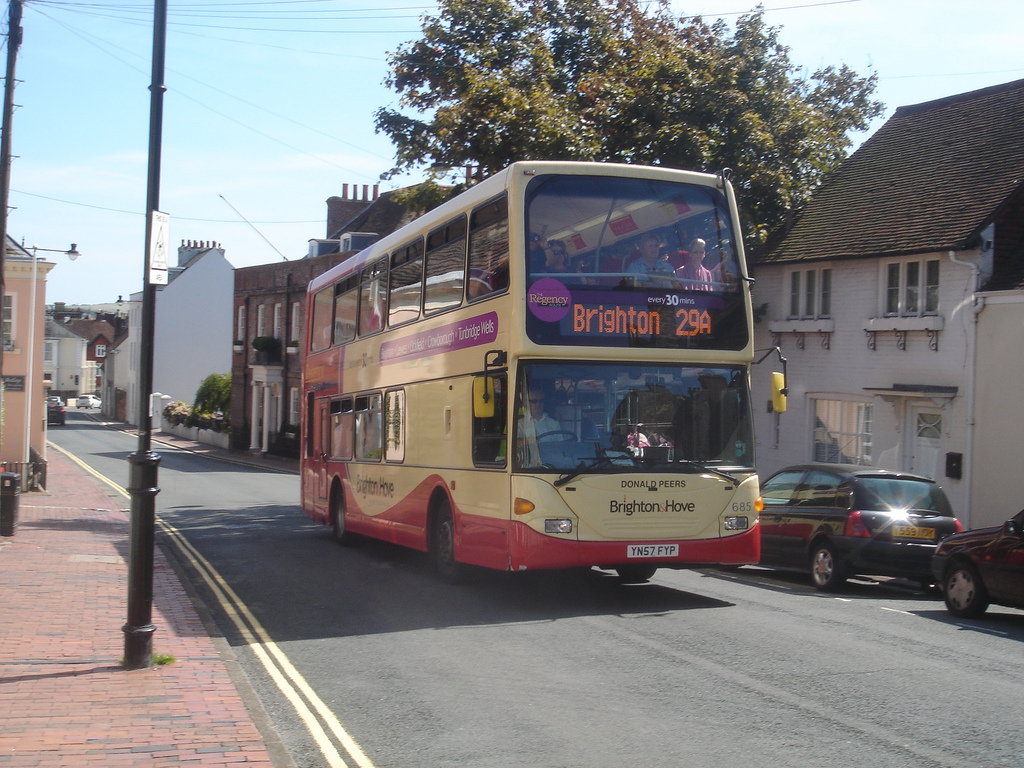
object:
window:
[800, 267, 819, 323]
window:
[922, 258, 941, 317]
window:
[290, 386, 302, 429]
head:
[640, 232, 662, 257]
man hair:
[639, 231, 663, 248]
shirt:
[627, 256, 677, 289]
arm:
[624, 262, 642, 289]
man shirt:
[676, 263, 715, 292]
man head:
[688, 237, 707, 263]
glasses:
[690, 248, 707, 255]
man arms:
[662, 261, 683, 288]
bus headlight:
[543, 517, 575, 535]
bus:
[299, 159, 785, 587]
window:
[901, 259, 924, 317]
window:
[809, 396, 874, 468]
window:
[913, 411, 946, 441]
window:
[238, 307, 249, 344]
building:
[230, 181, 397, 462]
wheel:
[325, 479, 356, 548]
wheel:
[428, 494, 475, 582]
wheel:
[807, 542, 849, 591]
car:
[745, 461, 977, 595]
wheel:
[940, 563, 988, 620]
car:
[923, 506, 1020, 622]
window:
[787, 270, 804, 320]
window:
[817, 265, 836, 321]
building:
[759, 77, 1024, 532]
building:
[967, 282, 1023, 555]